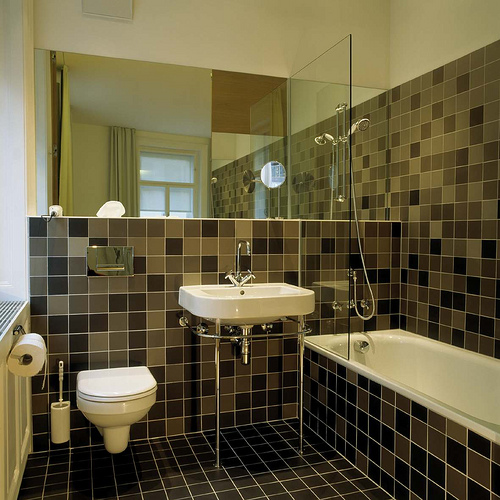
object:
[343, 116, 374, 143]
shower head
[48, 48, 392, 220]
mirror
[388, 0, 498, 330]
wall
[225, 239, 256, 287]
sink fixture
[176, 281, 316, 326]
sink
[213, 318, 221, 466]
leg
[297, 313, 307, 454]
leg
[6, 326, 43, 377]
roll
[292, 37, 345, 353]
panel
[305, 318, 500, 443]
bathtub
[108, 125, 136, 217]
curtain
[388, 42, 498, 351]
tiles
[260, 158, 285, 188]
mirror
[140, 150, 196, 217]
blinds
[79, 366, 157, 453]
toilet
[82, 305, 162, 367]
tank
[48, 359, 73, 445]
brush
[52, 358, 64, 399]
handle